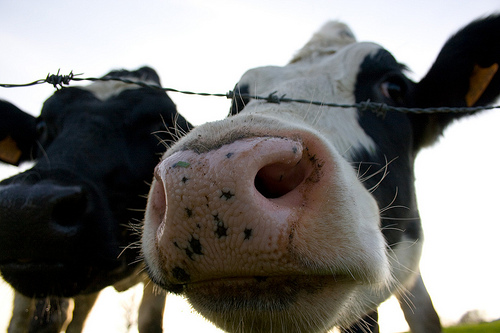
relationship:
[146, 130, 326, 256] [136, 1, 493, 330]
nostrils of cow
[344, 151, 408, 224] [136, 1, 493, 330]
whiskers of cow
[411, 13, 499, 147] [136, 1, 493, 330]
ear of cow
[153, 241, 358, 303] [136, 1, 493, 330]
mouth of cow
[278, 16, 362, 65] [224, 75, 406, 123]
hump between eyes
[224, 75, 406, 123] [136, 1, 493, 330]
eyes of cow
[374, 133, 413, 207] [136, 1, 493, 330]
fur of cow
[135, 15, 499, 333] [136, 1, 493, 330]
head of cow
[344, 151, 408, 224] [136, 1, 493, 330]
whiskers on cow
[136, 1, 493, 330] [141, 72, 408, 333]
cow has face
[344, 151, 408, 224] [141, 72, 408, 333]
whiskers on face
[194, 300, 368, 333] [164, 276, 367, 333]
whiskers of chin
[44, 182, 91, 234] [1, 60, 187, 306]
nostril of cow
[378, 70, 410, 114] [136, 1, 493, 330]
eye of cow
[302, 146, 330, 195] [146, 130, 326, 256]
dirt in nostrils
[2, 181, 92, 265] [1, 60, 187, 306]
nose of cow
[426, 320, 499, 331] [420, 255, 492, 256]
grass in background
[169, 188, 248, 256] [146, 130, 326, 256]
spots on nostrils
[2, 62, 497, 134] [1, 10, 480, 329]
wire in front of cows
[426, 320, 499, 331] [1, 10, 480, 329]
grass behind cows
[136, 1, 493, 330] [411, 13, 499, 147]
cow has ear